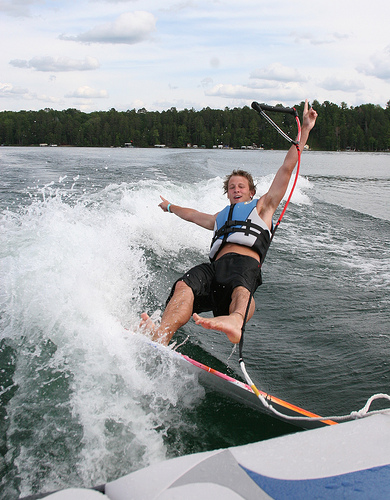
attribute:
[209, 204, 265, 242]
jacket — blue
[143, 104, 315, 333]
man — white, surfing, boarding, young, happy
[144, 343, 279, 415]
board — orange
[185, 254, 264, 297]
shorts — black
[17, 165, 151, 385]
water — white, clear, blue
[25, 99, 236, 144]
trees — green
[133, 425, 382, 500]
boat — white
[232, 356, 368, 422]
rope — white